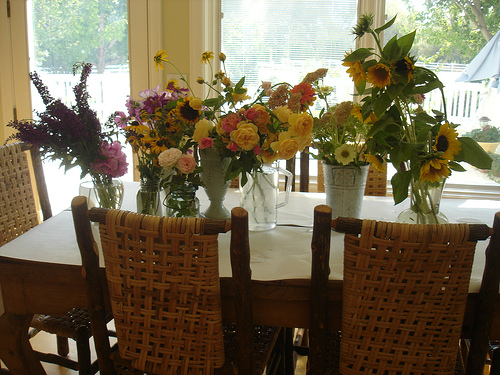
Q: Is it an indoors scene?
A: Yes, it is indoors.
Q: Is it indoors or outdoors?
A: It is indoors.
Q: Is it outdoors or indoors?
A: It is indoors.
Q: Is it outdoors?
A: No, it is indoors.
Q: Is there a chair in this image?
A: Yes, there is a chair.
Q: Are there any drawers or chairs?
A: Yes, there is a chair.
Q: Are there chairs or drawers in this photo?
A: Yes, there is a chair.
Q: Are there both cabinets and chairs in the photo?
A: No, there is a chair but no cabinets.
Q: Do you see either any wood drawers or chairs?
A: Yes, there is a wood chair.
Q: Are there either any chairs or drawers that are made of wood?
A: Yes, the chair is made of wood.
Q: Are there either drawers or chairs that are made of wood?
A: Yes, the chair is made of wood.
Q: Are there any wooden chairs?
A: Yes, there is a wood chair.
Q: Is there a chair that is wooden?
A: Yes, there is a chair that is wooden.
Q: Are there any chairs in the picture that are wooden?
A: Yes, there is a chair that is wooden.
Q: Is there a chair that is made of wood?
A: Yes, there is a chair that is made of wood.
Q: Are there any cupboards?
A: No, there are no cupboards.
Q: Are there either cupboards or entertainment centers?
A: No, there are no cupboards or entertainment centers.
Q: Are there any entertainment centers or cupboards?
A: No, there are no cupboards or entertainment centers.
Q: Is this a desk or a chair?
A: This is a chair.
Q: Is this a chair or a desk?
A: This is a chair.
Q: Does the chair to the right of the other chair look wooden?
A: Yes, the chair is wooden.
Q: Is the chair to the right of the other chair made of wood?
A: Yes, the chair is made of wood.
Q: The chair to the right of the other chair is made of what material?
A: The chair is made of wood.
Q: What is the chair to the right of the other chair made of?
A: The chair is made of wood.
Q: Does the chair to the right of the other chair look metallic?
A: No, the chair is wooden.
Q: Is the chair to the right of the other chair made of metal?
A: No, the chair is made of wood.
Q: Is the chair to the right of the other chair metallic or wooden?
A: The chair is wooden.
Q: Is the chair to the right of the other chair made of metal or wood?
A: The chair is made of wood.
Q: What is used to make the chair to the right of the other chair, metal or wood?
A: The chair is made of wood.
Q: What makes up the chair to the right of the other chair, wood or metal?
A: The chair is made of wood.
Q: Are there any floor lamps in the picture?
A: No, there are no floor lamps.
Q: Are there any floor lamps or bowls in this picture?
A: No, there are no floor lamps or bowls.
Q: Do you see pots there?
A: No, there are no pots.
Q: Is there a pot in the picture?
A: No, there are no pots.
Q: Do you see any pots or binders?
A: No, there are no pots or binders.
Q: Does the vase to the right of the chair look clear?
A: Yes, the vase is clear.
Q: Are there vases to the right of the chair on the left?
A: Yes, there is a vase to the right of the chair.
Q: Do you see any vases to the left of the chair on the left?
A: No, the vase is to the right of the chair.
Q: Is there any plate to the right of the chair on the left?
A: No, there is a vase to the right of the chair.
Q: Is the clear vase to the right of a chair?
A: Yes, the vase is to the right of a chair.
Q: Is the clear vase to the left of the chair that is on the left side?
A: No, the vase is to the right of the chair.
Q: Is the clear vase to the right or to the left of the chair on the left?
A: The vase is to the right of the chair.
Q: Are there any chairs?
A: Yes, there is a chair.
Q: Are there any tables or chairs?
A: Yes, there is a chair.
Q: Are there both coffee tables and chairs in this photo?
A: No, there is a chair but no coffee tables.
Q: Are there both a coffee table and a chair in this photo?
A: No, there is a chair but no coffee tables.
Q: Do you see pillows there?
A: No, there are no pillows.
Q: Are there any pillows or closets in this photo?
A: No, there are no pillows or closets.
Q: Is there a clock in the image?
A: No, there are no clocks.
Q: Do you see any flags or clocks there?
A: No, there are no clocks or flags.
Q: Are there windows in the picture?
A: Yes, there is a window.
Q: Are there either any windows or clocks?
A: Yes, there is a window.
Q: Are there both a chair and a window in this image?
A: Yes, there are both a window and a chair.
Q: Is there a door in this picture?
A: No, there are no doors.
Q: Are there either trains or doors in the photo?
A: No, there are no doors or trains.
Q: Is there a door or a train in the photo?
A: No, there are no doors or trains.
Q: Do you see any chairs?
A: Yes, there is a chair.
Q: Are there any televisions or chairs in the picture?
A: Yes, there is a chair.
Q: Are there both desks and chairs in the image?
A: No, there is a chair but no desks.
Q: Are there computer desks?
A: No, there are no computer desks.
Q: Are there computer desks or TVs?
A: No, there are no computer desks or tvs.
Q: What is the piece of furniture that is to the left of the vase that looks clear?
A: The piece of furniture is a chair.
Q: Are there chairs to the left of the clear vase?
A: Yes, there is a chair to the left of the vase.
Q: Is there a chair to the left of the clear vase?
A: Yes, there is a chair to the left of the vase.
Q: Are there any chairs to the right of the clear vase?
A: No, the chair is to the left of the vase.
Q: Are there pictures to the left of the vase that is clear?
A: No, there is a chair to the left of the vase.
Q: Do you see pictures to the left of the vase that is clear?
A: No, there is a chair to the left of the vase.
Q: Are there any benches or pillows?
A: No, there are no pillows or benches.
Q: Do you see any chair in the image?
A: Yes, there is a chair.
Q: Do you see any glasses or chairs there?
A: Yes, there is a chair.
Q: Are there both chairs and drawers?
A: No, there is a chair but no drawers.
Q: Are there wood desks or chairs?
A: Yes, there is a wood chair.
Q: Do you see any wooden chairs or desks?
A: Yes, there is a wood chair.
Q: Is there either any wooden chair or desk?
A: Yes, there is a wood chair.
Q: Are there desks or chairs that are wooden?
A: Yes, the chair is wooden.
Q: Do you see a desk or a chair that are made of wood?
A: Yes, the chair is made of wood.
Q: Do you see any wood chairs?
A: Yes, there is a chair that is made of wood.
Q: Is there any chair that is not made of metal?
A: Yes, there is a chair that is made of wood.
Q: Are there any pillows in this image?
A: No, there are no pillows.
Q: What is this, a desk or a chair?
A: This is a chair.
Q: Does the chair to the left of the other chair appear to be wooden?
A: Yes, the chair is wooden.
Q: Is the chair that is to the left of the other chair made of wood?
A: Yes, the chair is made of wood.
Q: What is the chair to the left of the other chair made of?
A: The chair is made of wood.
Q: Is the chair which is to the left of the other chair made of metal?
A: No, the chair is made of wood.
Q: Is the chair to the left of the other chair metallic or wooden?
A: The chair is wooden.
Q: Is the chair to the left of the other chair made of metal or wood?
A: The chair is made of wood.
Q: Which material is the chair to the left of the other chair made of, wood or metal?
A: The chair is made of wood.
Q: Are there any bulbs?
A: No, there are no bulbs.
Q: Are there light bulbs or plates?
A: No, there are no light bulbs or plates.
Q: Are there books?
A: No, there are no books.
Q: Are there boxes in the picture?
A: No, there are no boxes.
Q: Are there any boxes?
A: No, there are no boxes.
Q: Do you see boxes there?
A: No, there are no boxes.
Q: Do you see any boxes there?
A: No, there are no boxes.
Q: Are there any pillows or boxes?
A: No, there are no boxes or pillows.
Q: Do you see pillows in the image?
A: No, there are no pillows.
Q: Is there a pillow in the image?
A: No, there are no pillows.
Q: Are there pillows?
A: No, there are no pillows.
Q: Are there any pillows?
A: No, there are no pillows.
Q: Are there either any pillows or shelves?
A: No, there are no pillows or shelves.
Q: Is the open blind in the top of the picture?
A: Yes, the blind is in the top of the image.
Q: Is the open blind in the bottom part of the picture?
A: No, the blind is in the top of the image.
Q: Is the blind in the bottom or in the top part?
A: The blind is in the top of the image.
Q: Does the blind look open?
A: Yes, the blind is open.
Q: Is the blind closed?
A: No, the blind is open.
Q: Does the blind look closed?
A: No, the blind is open.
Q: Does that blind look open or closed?
A: The blind is open.